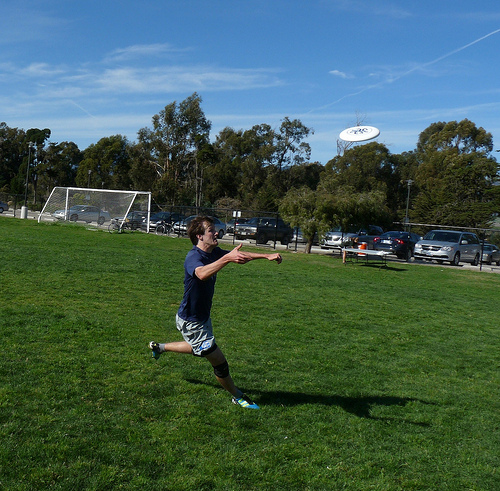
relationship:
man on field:
[149, 215, 284, 413] [2, 213, 497, 490]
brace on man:
[213, 360, 231, 377] [149, 215, 284, 413]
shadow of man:
[186, 374, 451, 430] [149, 215, 284, 413]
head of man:
[184, 217, 220, 247] [149, 215, 284, 413]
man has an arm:
[149, 215, 284, 413] [188, 249, 230, 281]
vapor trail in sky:
[298, 30, 498, 117] [0, 0, 499, 159]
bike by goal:
[154, 218, 175, 237] [37, 184, 154, 235]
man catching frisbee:
[149, 215, 284, 413] [337, 124, 383, 146]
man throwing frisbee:
[149, 215, 284, 413] [337, 124, 383, 146]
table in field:
[339, 247, 389, 271] [2, 213, 497, 490]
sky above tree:
[0, 0, 499, 159] [318, 144, 403, 246]